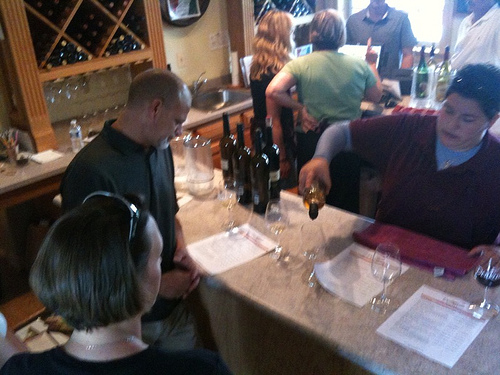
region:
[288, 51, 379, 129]
a green shirt on a woman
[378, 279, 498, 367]
a paper on a bar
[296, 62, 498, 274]
a man pouring a drink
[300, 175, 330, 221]
a bottle in a man's hand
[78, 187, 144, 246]
glasses on a woman's head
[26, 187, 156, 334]
short brown hair on a woman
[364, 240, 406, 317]
an empty wine glass on a bar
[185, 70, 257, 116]
a metal sink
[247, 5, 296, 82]
wavy blond hair on a woman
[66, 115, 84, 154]
a bottle of water on a counter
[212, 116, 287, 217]
wine bottles on a counter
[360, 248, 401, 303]
wine glass on counter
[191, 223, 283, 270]
pieces of paper on counter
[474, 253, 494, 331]
glass with wine iin it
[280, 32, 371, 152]
green shirt on woman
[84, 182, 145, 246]
sunglasses on head of woman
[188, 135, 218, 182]
large glass container on counter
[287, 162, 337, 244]
bottle of wine in hand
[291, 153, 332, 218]
bottle of wine being poured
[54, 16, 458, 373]
people wine tasting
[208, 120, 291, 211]
several bottles of wine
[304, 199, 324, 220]
black tip of wine bottle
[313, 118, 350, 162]
grey undershirt of person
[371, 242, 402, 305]
empty glass on counter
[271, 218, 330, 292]
empty glass on counter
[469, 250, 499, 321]
wine in wine glasss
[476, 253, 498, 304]
red wine in glass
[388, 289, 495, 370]
paper on the counter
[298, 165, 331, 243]
Woman pouring wine into a glass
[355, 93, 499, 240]
woman wearing a red shirt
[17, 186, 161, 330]
woman with black hair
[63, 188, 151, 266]
woman wearing black sunglasses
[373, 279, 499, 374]
menu on the table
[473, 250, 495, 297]
glass of wine on the table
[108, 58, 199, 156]
man with a balding head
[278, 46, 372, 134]
woman wearing a green shirt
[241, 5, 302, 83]
woman with blond hair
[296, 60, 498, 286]
Person pouring wine into a glass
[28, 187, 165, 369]
Woman with sunglasses on top of her head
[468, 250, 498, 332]
Wine in a glass on the table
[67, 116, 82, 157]
Bottle of water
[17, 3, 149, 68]
Bottle of wine in a wine holder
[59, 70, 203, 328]
Man leaning against the counter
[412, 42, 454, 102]
Bottles of wine on the counter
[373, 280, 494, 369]
Tasting notes on the counter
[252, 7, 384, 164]
Two women behind the counter